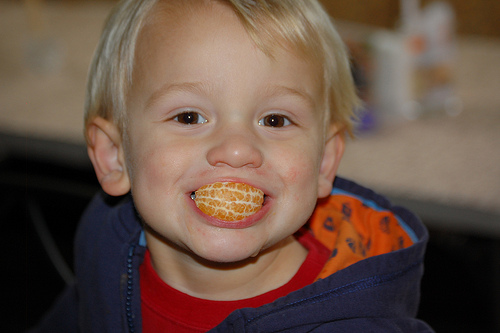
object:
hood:
[239, 175, 430, 331]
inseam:
[307, 192, 411, 282]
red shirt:
[139, 232, 329, 333]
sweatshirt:
[40, 179, 437, 331]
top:
[132, 225, 327, 333]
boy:
[33, 2, 435, 333]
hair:
[82, 0, 372, 148]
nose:
[206, 115, 262, 168]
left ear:
[86, 114, 132, 196]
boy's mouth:
[185, 177, 275, 228]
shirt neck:
[134, 229, 315, 312]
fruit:
[194, 181, 265, 220]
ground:
[288, 48, 326, 101]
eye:
[257, 113, 299, 129]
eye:
[167, 110, 211, 126]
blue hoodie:
[31, 171, 437, 333]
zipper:
[125, 231, 134, 333]